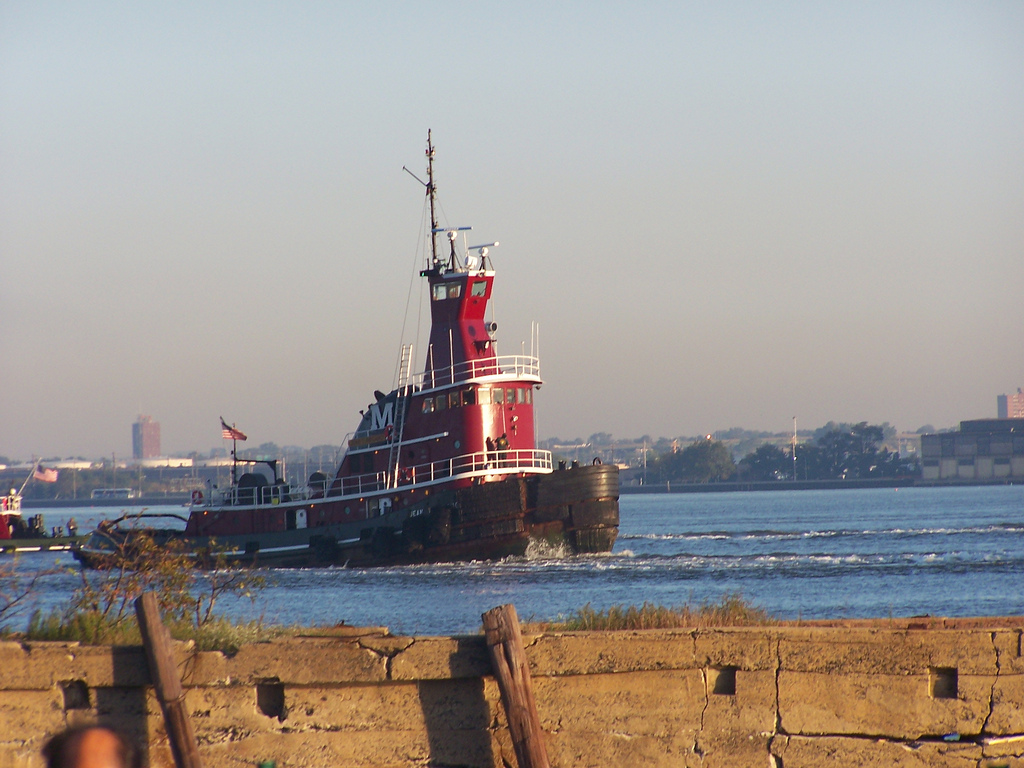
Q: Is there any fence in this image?
A: No, there are no fences.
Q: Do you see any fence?
A: No, there are no fences.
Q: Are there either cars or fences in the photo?
A: No, there are no fences or cars.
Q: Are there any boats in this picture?
A: Yes, there is a boat.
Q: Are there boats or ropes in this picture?
A: Yes, there is a boat.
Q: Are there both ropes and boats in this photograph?
A: No, there is a boat but no ropes.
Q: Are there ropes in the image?
A: No, there are no ropes.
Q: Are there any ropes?
A: No, there are no ropes.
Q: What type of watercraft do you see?
A: The watercraft is a boat.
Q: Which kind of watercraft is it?
A: The watercraft is a boat.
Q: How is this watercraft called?
A: This is a boat.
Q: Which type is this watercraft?
A: This is a boat.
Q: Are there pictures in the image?
A: No, there are no pictures.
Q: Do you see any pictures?
A: No, there are no pictures.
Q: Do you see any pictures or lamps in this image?
A: No, there are no pictures or lamps.